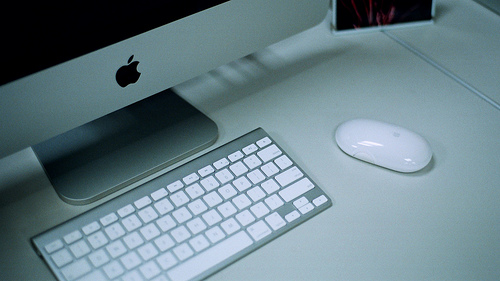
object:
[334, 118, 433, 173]
mouse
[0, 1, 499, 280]
desk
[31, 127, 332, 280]
keyboard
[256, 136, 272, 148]
button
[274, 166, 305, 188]
button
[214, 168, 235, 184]
button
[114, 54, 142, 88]
apple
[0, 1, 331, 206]
computer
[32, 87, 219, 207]
leg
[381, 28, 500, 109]
cord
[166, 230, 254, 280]
space bar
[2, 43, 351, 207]
shadow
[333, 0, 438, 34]
card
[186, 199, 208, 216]
key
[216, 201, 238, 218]
key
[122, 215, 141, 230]
key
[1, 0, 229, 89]
screen